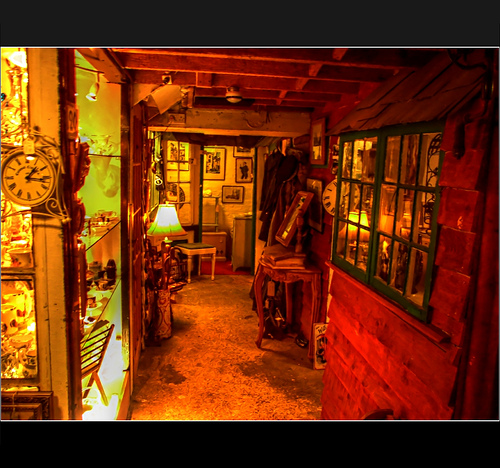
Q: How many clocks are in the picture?
A: 2.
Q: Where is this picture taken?
A: In a shop.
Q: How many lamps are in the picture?
A: 2.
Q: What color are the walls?
A: Brown.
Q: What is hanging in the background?
A: Coats.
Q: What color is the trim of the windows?
A: Green.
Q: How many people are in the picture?
A: Zero.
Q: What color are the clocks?
A: White.